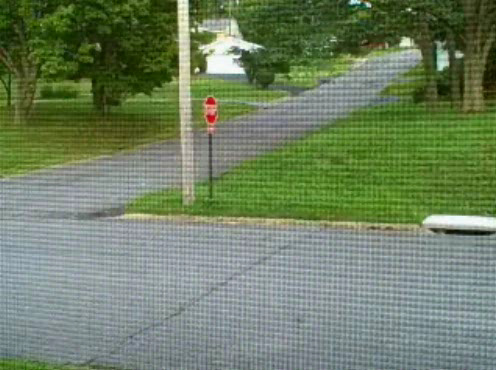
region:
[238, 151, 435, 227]
green grass growing by road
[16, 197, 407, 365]
paved road in suburb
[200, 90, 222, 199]
stop sign on curb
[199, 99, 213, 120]
white rim of stop sign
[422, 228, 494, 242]
storm drain by road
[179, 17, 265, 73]
white house in background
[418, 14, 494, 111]
trees growing on right of road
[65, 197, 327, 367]
long crack in paved road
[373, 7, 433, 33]
green leaves of tall tree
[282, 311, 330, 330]
dark spot on paved road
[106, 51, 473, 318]
view is at a road way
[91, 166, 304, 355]
two roads are at a rightangle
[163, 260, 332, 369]
the roads are made of asphalt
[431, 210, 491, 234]
a bench is next to the road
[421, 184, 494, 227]
the bench is white in color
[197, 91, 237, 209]
thr street light is red in color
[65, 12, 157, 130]
trees are next to the fild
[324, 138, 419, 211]
floor is coverd of grasses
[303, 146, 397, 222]
the grasse are green in color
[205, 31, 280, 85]
buildings are seen at the background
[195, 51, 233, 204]
a stop sign on the grass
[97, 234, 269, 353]
a long crack in the road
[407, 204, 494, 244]
a white thing on side of road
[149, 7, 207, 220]
a tall wooden pole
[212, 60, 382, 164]
a road running through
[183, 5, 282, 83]
a big white house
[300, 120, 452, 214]
a lot of green grass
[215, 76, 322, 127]
a small path leading by trees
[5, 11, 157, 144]
two big trees in the grass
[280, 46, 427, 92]
a road on a hill